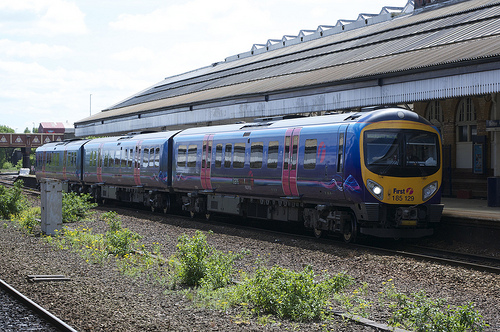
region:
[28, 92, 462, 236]
this is a train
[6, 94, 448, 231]
this is a passenger train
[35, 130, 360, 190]
windows on the train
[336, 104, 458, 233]
yellow front of the train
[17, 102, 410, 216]
the train is blue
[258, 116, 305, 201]
red doors on the train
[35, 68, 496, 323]
the train is on the tracks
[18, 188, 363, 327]
weeds next to the tracks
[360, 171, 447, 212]
headlights on the train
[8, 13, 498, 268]
train is at the station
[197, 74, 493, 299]
a train on the track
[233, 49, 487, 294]
a train on the train tracks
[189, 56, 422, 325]
a passenger train on the train tracksk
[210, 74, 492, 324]
a passenger train on the tracks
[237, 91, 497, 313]
a blue train on the tracks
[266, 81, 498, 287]
a blue train on the train tracks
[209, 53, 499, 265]
a blue passenger train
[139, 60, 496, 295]
a blue passenger train on the track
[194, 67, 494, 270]
a blue passenger train on the train tracks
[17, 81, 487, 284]
a short train on the tracks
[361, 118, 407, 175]
window of a train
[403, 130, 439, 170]
window of a train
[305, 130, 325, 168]
window of a train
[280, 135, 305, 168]
window of a train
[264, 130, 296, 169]
window of a train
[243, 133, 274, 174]
window of a train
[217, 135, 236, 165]
window of a train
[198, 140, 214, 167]
window of a train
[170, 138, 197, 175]
window of a train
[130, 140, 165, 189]
window of a train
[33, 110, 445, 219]
train with three cars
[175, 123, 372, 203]
Blue and pink train car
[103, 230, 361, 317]
bushes growing between the track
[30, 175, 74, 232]
Electrical box on train track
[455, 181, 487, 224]
platform for passengers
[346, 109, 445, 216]
Yellow front of train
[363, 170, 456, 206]
headlights of yellow train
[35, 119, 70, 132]
Rooftop behind the train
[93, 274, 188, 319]
gravel between the train tracks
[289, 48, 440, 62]
Shingled roof of train station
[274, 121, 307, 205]
train's door is pink